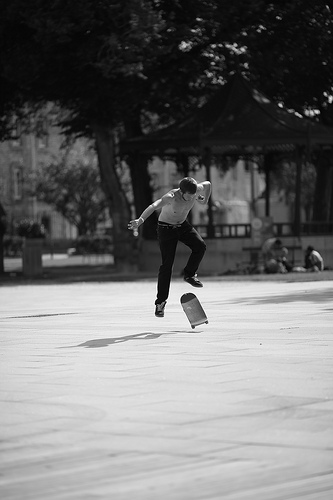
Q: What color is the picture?
A: Black & White.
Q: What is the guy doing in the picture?
A: Skateboarding.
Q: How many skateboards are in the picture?
A: One.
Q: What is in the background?
A: Trees.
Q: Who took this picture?
A: Neighbor.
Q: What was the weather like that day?
A: Hot.